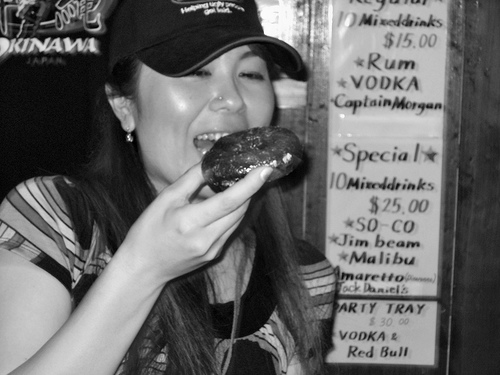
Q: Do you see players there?
A: No, there are no players.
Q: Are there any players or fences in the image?
A: No, there are no players or fences.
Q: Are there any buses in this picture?
A: No, there are no buses.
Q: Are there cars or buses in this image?
A: No, there are no buses or cars.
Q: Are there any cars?
A: No, there are no cars.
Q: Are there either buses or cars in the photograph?
A: No, there are no cars or buses.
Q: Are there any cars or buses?
A: No, there are no cars or buses.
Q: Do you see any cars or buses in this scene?
A: No, there are no cars or buses.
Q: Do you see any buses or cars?
A: No, there are no cars or buses.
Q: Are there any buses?
A: No, there are no buses.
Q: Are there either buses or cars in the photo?
A: No, there are no buses or cars.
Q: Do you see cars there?
A: No, there are no cars.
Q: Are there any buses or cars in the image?
A: No, there are no cars or buses.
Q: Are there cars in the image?
A: No, there are no cars.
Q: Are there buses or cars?
A: No, there are no cars or buses.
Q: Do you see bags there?
A: No, there are no bags.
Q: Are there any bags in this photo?
A: No, there are no bags.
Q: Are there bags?
A: No, there are no bags.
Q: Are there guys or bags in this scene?
A: No, there are no bags or guys.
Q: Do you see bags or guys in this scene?
A: No, there are no bags or guys.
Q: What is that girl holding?
A: The girl is holding the doughnut.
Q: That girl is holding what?
A: The girl is holding the doughnut.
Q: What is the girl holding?
A: The girl is holding the doughnut.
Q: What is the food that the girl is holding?
A: The food is a donut.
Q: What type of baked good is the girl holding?
A: The girl is holding the donut.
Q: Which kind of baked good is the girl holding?
A: The girl is holding the donut.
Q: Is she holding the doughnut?
A: Yes, the girl is holding the doughnut.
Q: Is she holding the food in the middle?
A: Yes, the girl is holding the doughnut.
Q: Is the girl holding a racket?
A: No, the girl is holding the doughnut.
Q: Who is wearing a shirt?
A: The girl is wearing a shirt.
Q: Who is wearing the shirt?
A: The girl is wearing a shirt.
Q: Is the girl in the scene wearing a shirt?
A: Yes, the girl is wearing a shirt.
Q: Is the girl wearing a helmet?
A: No, the girl is wearing a shirt.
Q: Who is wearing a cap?
A: The girl is wearing a cap.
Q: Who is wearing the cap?
A: The girl is wearing a cap.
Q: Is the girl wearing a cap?
A: Yes, the girl is wearing a cap.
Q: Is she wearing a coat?
A: No, the girl is wearing a cap.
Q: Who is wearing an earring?
A: The girl is wearing an earring.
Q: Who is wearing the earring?
A: The girl is wearing an earring.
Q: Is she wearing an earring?
A: Yes, the girl is wearing an earring.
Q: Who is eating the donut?
A: The girl is eating the donut.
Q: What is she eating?
A: The girl is eating a donut.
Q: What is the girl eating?
A: The girl is eating a donut.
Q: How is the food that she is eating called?
A: The food is a donut.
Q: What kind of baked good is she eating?
A: The girl is eating a donut.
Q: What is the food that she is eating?
A: The food is a donut.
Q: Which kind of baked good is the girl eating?
A: The girl is eating a donut.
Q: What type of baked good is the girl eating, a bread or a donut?
A: The girl is eating a donut.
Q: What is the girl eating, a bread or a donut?
A: The girl is eating a donut.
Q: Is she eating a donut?
A: Yes, the girl is eating a donut.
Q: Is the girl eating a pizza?
A: No, the girl is eating a donut.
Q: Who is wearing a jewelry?
A: The girl is wearing a jewelry.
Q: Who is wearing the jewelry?
A: The girl is wearing a jewelry.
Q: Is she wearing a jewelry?
A: Yes, the girl is wearing a jewelry.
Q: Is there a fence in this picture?
A: No, there are no fences.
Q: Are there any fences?
A: No, there are no fences.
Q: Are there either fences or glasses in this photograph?
A: No, there are no fences or glasses.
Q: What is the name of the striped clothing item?
A: The clothing item is a shirt.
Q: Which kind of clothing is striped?
A: The clothing is a shirt.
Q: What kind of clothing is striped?
A: The clothing is a shirt.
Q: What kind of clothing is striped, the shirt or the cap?
A: The shirt is striped.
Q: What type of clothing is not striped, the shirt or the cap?
A: The cap is not striped.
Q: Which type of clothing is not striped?
A: The clothing is a cap.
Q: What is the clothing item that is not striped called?
A: The clothing item is a cap.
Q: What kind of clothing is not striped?
A: The clothing is a cap.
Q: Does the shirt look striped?
A: Yes, the shirt is striped.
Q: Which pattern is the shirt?
A: The shirt is striped.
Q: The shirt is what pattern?
A: The shirt is striped.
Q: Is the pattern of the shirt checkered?
A: No, the shirt is striped.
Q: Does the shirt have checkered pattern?
A: No, the shirt is striped.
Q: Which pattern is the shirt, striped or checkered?
A: The shirt is striped.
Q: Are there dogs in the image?
A: No, there are no dogs.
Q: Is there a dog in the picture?
A: No, there are no dogs.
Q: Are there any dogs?
A: No, there are no dogs.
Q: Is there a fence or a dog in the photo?
A: No, there are no dogs or fences.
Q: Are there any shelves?
A: No, there are no shelves.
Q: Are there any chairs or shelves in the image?
A: No, there are no shelves or chairs.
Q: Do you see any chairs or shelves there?
A: No, there are no shelves or chairs.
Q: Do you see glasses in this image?
A: No, there are no glasses.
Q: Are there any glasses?
A: No, there are no glasses.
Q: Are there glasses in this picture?
A: No, there are no glasses.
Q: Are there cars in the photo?
A: No, there are no cars.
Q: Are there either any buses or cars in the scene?
A: No, there are no cars or buses.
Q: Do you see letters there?
A: Yes, there are letters.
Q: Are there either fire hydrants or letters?
A: Yes, there are letters.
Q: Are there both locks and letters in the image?
A: No, there are letters but no locks.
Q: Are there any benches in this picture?
A: No, there are no benches.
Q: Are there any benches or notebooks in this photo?
A: No, there are no benches or notebooks.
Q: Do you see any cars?
A: No, there are no cars.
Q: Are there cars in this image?
A: No, there are no cars.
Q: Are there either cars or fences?
A: No, there are no cars or fences.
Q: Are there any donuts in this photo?
A: Yes, there is a donut.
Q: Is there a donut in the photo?
A: Yes, there is a donut.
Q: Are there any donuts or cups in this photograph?
A: Yes, there is a donut.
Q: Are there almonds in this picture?
A: No, there are no almonds.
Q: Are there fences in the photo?
A: No, there are no fences.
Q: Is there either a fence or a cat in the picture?
A: No, there are no fences or cats.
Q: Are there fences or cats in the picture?
A: No, there are no fences or cats.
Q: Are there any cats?
A: No, there are no cats.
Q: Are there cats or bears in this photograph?
A: No, there are no cats or bears.